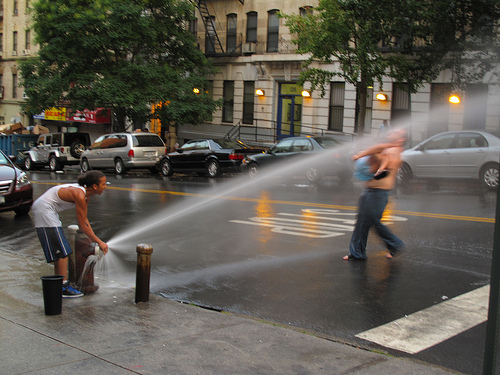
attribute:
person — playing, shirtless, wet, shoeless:
[342, 128, 409, 260]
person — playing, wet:
[354, 154, 388, 179]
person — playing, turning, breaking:
[31, 170, 106, 298]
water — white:
[78, 98, 499, 294]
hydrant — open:
[75, 229, 98, 293]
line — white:
[355, 284, 498, 353]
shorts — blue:
[36, 227, 71, 262]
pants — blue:
[350, 188, 405, 261]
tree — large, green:
[17, 0, 225, 132]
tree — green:
[276, 0, 499, 134]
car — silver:
[81, 133, 166, 173]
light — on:
[255, 90, 263, 95]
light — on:
[302, 88, 308, 96]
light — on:
[377, 95, 387, 100]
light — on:
[448, 97, 458, 102]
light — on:
[194, 87, 199, 93]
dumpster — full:
[0, 136, 37, 160]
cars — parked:
[25, 132, 499, 187]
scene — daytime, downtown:
[1, 1, 500, 374]